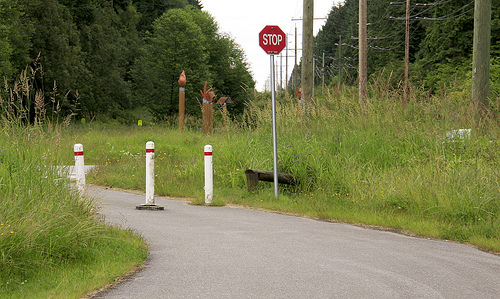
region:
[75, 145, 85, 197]
white metal pole with red stripe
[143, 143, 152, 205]
white metal pole with red stripe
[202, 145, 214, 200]
white metal pole with red stripe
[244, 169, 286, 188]
black tree trunk on ground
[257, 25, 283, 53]
red sign on pole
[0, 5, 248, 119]
green trees in background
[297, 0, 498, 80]
green trees in background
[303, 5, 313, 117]
wooden pole in grass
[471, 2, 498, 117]
wooden pole in grass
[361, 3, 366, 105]
wooden pole in grass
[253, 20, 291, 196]
red stop sign on silver pole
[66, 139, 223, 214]
white blockades in roadway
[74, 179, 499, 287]
road cutting through grass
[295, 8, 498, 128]
three utility poles on right side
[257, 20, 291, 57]
red sign with white lettering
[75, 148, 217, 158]
red stripe at top of white poles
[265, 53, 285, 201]
silver pole stop sign is on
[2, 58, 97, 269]
long grass growing on left side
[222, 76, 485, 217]
long grass growing on right side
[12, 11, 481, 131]
trees growing in background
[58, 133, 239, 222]
a barrier in the road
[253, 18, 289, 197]
a stop sign on a pole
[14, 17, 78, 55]
the leaves of a trees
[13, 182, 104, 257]
grass on the side of the road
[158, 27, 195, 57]
the leaves of a tree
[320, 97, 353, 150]
tall grass on the side of he road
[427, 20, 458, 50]
the leaves of a trees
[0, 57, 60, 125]
the tops of a tall grass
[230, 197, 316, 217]
the edge of a road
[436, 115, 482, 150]
trash in the grass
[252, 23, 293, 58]
red and white sign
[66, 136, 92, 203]
red and white pole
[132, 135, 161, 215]
red and white pole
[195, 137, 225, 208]
red and white pole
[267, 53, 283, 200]
long silver pole sticking out of the ground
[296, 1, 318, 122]
long wooden telephone pole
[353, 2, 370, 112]
long wooden telephone pole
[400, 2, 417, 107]
long wooden telephone pole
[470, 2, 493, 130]
long wooden telephone pole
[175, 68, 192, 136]
wooden pole with design on top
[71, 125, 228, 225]
three white road posts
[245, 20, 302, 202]
red stop sign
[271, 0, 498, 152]
phone lines with wooden posts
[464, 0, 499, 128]
wooden post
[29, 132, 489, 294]
asphalt walking trail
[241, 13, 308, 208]
stop sign in a grassy meadow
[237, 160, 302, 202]
broken wooden post in grass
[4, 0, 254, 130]
edge of forest with green trees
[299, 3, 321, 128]
wooden post of electrical line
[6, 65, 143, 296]
tall green and brown grass